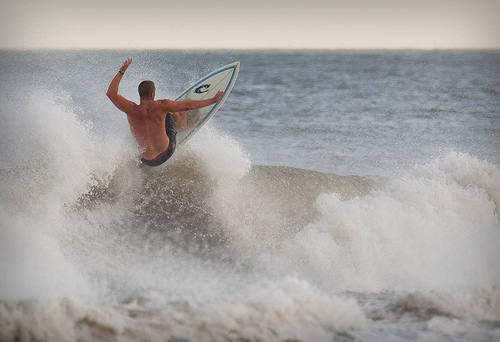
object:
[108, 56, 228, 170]
man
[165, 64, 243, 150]
surfboard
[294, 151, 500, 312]
wave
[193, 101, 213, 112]
design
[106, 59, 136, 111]
arm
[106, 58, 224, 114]
arm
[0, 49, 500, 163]
ripples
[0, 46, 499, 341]
water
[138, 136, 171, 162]
behind